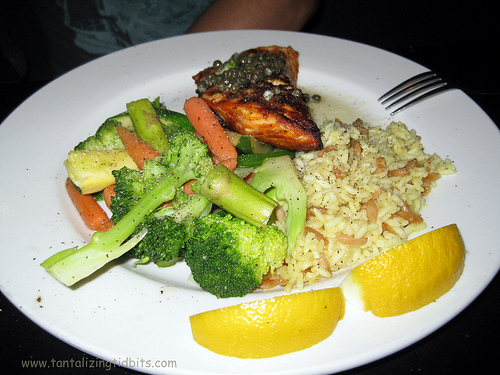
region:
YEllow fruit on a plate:
[178, 289, 280, 374]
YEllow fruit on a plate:
[342, 239, 471, 324]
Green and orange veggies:
[73, 95, 256, 285]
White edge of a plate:
[102, 322, 157, 374]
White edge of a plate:
[29, 309, 84, 355]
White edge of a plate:
[3, 65, 63, 122]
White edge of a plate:
[162, 1, 349, 66]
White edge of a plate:
[345, 321, 497, 371]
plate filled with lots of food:
[1, 30, 494, 373]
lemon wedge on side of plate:
[177, 288, 351, 348]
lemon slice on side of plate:
[344, 220, 478, 329]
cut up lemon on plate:
[175, 220, 471, 351]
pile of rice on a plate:
[307, 125, 425, 245]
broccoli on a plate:
[110, 171, 275, 311]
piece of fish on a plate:
[194, 48, 306, 143]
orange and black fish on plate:
[212, 39, 293, 140]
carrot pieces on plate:
[101, 119, 174, 171]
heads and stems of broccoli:
[157, 165, 282, 290]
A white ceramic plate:
[0, 28, 499, 373]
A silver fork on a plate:
[376, 70, 477, 117]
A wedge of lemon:
[341, 220, 470, 320]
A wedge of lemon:
[188, 284, 343, 356]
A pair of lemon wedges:
[188, 218, 466, 364]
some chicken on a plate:
[193, 45, 324, 151]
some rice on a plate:
[261, 118, 455, 290]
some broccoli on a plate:
[43, 95, 304, 300]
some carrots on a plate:
[63, 98, 237, 235]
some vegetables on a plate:
[38, 91, 305, 299]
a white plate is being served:
[3, 4, 493, 373]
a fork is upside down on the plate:
[375, 51, 495, 116]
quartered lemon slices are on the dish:
[185, 225, 475, 351]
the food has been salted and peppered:
[55, 81, 446, 271]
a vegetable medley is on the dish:
[55, 101, 297, 301]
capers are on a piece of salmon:
[182, 41, 318, 157]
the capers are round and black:
[205, 46, 307, 96]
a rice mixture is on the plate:
[260, 120, 440, 275]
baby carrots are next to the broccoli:
[130, 96, 235, 281]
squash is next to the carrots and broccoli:
[61, 147, 129, 195]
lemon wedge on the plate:
[357, 219, 469, 323]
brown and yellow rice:
[317, 115, 454, 238]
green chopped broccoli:
[55, 79, 310, 304]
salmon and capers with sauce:
[191, 40, 326, 155]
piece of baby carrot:
[189, 92, 244, 174]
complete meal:
[34, 30, 467, 366]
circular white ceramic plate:
[2, 8, 497, 373]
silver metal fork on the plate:
[371, 50, 497, 131]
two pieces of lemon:
[156, 218, 473, 364]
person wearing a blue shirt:
[38, 5, 323, 55]